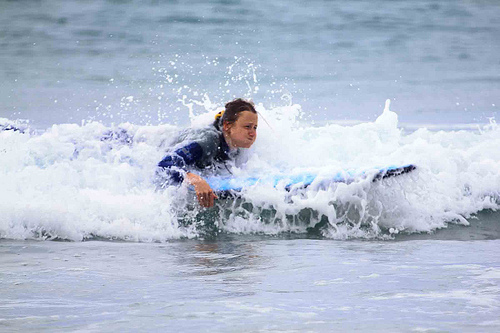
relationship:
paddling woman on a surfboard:
[151, 97, 260, 207] [112, 160, 416, 200]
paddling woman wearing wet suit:
[0, 97, 257, 207] [0, 106, 237, 174]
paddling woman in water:
[0, 97, 257, 207] [2, 3, 497, 329]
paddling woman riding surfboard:
[0, 97, 257, 207] [187, 158, 446, 223]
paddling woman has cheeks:
[0, 97, 257, 207] [228, 122, 256, 147]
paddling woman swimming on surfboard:
[0, 97, 257, 207] [172, 155, 424, 205]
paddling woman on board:
[0, 97, 257, 207] [161, 157, 424, 201]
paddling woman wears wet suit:
[0, 97, 257, 207] [0, 120, 241, 187]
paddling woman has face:
[0, 97, 257, 207] [233, 111, 258, 148]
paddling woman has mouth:
[0, 97, 257, 207] [244, 135, 254, 146]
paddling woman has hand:
[0, 97, 257, 207] [185, 173, 217, 208]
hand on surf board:
[185, 173, 217, 208] [177, 153, 417, 198]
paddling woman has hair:
[0, 97, 257, 207] [213, 98, 257, 125]